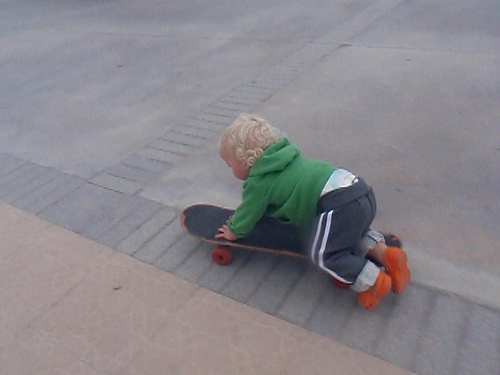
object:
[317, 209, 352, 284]
stripes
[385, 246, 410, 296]
shoe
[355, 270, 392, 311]
shoe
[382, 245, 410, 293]
feet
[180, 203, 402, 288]
skateboard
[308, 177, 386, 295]
pants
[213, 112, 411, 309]
boy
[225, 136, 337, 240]
hoodie